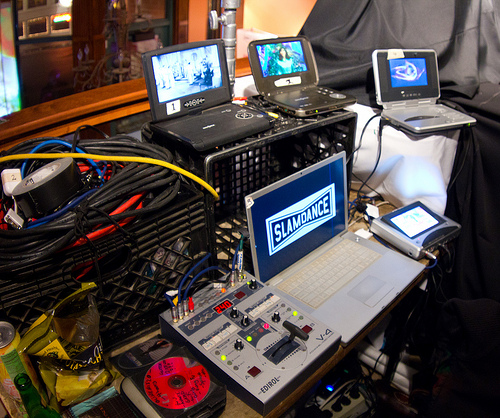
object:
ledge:
[4, 76, 152, 146]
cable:
[0, 148, 219, 205]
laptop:
[244, 149, 429, 345]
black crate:
[145, 100, 278, 157]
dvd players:
[246, 35, 357, 122]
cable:
[87, 204, 133, 243]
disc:
[140, 350, 212, 411]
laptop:
[371, 46, 475, 138]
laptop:
[139, 39, 272, 146]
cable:
[174, 247, 213, 305]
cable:
[183, 263, 232, 300]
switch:
[268, 315, 309, 367]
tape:
[6, 154, 83, 221]